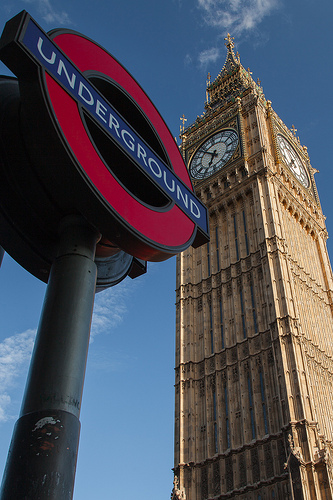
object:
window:
[243, 313, 247, 339]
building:
[173, 30, 332, 498]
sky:
[0, 0, 333, 499]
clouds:
[0, 0, 333, 499]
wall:
[178, 27, 333, 498]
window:
[260, 401, 267, 411]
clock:
[188, 125, 239, 179]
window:
[250, 243, 253, 245]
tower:
[174, 30, 332, 499]